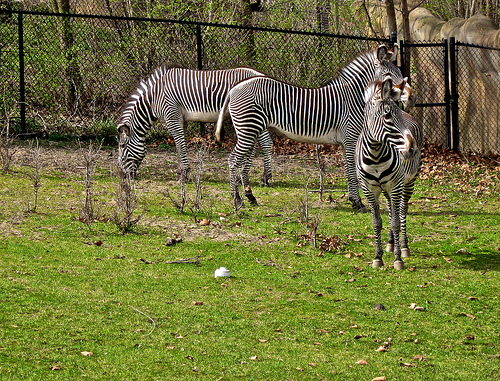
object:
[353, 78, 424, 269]
zebra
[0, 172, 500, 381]
grass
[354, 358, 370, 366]
leaf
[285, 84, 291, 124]
stripes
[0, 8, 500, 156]
fence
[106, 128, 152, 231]
plant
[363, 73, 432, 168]
head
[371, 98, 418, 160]
face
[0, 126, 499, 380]
ground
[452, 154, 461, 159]
leaves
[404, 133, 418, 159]
nose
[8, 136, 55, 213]
bushes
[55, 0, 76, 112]
trees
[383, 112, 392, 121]
eye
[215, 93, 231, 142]
tail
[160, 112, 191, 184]
legs